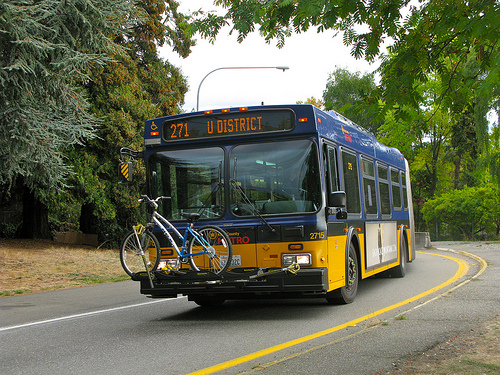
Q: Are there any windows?
A: Yes, there is a window.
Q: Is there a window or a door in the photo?
A: Yes, there is a window.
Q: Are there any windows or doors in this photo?
A: Yes, there is a window.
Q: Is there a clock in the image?
A: No, there are no clocks.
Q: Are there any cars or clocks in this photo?
A: No, there are no clocks or cars.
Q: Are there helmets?
A: No, there are no helmets.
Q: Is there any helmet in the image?
A: No, there are no helmets.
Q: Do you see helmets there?
A: No, there are no helmets.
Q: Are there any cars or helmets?
A: No, there are no helmets or cars.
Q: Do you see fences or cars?
A: No, there are no cars or fences.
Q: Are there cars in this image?
A: No, there are no cars.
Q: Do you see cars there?
A: No, there are no cars.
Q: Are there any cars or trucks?
A: No, there are no cars or trucks.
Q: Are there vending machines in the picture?
A: No, there are no vending machines.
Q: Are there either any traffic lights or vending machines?
A: No, there are no vending machines or traffic lights.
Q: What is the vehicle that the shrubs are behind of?
A: The vehicle is a bus.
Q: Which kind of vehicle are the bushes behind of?
A: The shrubs are behind the bus.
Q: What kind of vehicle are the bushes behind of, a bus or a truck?
A: The bushes are behind a bus.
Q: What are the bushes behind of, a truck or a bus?
A: The bushes are behind a bus.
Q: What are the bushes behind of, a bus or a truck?
A: The bushes are behind a bus.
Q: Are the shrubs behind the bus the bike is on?
A: Yes, the shrubs are behind the bus.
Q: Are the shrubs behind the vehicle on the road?
A: Yes, the shrubs are behind the bus.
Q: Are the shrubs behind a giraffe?
A: No, the shrubs are behind the bus.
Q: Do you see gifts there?
A: No, there are no gifts.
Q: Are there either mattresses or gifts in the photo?
A: No, there are no gifts or mattresses.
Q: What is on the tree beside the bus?
A: The leaves are on the tree.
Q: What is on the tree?
A: The leaves are on the tree.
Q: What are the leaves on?
A: The leaves are on the tree.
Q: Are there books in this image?
A: No, there are no books.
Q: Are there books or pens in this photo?
A: No, there are no books or pens.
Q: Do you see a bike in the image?
A: Yes, there is a bike.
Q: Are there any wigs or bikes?
A: Yes, there is a bike.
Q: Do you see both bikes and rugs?
A: No, there is a bike but no rugs.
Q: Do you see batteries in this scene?
A: No, there are no batteries.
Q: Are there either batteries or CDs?
A: No, there are no batteries or cds.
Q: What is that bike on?
A: The bike is on the bus.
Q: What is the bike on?
A: The bike is on the bus.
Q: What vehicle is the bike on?
A: The bike is on the bus.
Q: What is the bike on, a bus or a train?
A: The bike is on a bus.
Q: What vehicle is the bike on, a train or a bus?
A: The bike is on a bus.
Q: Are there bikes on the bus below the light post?
A: Yes, there is a bike on the bus.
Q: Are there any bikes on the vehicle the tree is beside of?
A: Yes, there is a bike on the bus.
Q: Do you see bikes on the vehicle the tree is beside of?
A: Yes, there is a bike on the bus.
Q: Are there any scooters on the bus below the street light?
A: No, there is a bike on the bus.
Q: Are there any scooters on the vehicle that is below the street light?
A: No, there is a bike on the bus.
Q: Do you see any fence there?
A: No, there are no fences.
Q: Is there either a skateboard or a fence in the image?
A: No, there are no fences or skateboards.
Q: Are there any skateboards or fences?
A: No, there are no fences or skateboards.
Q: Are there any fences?
A: No, there are no fences.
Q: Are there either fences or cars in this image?
A: No, there are no fences or cars.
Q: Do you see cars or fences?
A: No, there are no fences or cars.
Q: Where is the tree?
A: The tree is on the road.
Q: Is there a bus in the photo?
A: Yes, there is a bus.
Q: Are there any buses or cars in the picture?
A: Yes, there is a bus.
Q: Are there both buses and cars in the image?
A: No, there is a bus but no cars.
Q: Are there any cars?
A: No, there are no cars.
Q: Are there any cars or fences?
A: No, there are no cars or fences.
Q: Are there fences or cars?
A: No, there are no cars or fences.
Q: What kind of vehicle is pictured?
A: The vehicle is a bus.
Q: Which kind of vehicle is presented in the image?
A: The vehicle is a bus.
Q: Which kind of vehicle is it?
A: The vehicle is a bus.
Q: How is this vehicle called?
A: This is a bus.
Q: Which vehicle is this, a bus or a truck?
A: This is a bus.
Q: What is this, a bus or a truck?
A: This is a bus.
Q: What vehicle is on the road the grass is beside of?
A: The vehicle is a bus.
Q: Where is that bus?
A: The bus is on the road.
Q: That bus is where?
A: The bus is on the road.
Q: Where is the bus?
A: The bus is on the road.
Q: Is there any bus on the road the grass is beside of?
A: Yes, there is a bus on the road.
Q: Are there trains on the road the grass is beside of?
A: No, there is a bus on the road.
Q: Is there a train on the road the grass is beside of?
A: No, there is a bus on the road.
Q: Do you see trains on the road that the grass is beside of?
A: No, there is a bus on the road.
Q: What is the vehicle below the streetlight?
A: The vehicle is a bus.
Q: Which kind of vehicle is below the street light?
A: The vehicle is a bus.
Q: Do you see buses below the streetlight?
A: Yes, there is a bus below the streetlight.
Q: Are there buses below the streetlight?
A: Yes, there is a bus below the streetlight.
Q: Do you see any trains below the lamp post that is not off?
A: No, there is a bus below the street lamp.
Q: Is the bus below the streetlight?
A: Yes, the bus is below the streetlight.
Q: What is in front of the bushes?
A: The bus is in front of the bushes.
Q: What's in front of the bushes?
A: The bus is in front of the bushes.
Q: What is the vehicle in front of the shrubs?
A: The vehicle is a bus.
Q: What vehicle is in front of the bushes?
A: The vehicle is a bus.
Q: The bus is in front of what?
A: The bus is in front of the shrubs.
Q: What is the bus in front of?
A: The bus is in front of the shrubs.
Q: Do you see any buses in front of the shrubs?
A: Yes, there is a bus in front of the shrubs.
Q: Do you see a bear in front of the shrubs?
A: No, there is a bus in front of the shrubs.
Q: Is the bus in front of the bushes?
A: Yes, the bus is in front of the bushes.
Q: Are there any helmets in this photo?
A: No, there are no helmets.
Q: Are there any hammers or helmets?
A: No, there are no helmets or hammers.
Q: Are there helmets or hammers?
A: No, there are no helmets or hammers.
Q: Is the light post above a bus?
A: Yes, the light post is above a bus.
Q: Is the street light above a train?
A: No, the street light is above a bus.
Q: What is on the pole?
A: The light post is on the pole.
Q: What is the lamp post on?
A: The lamp post is on the pole.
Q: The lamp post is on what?
A: The lamp post is on the pole.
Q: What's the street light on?
A: The lamp post is on the pole.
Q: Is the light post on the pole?
A: Yes, the light post is on the pole.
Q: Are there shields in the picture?
A: No, there are no shields.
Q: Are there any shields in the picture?
A: No, there are no shields.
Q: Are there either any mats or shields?
A: No, there are no shields or mats.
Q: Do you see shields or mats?
A: No, there are no shields or mats.